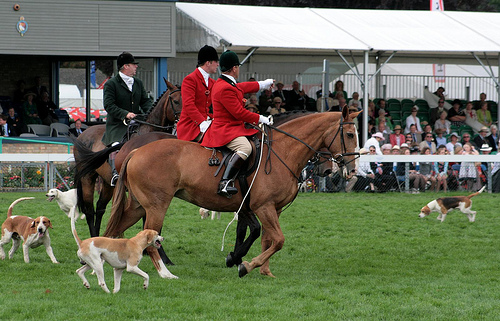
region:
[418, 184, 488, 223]
brown black and white dog on the grass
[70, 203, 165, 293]
brown and white dog on the grass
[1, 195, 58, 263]
brown and white dog on the grass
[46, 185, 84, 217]
white dog on the grass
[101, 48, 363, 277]
man in red riding a light brown horse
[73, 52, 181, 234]
man in black riding a brown and black horse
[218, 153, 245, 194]
a black leather riding boot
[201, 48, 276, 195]
a man in a red riding outfit with black hat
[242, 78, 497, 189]
people in the stands watching the horse riding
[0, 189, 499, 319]
green grass on horse riding field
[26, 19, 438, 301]
Horses on the grass.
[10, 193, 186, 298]
Dogs on the grass.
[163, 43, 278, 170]
Men riding horses on the field.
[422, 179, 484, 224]
Dog in the background.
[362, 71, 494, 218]
people watching the horses.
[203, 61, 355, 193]
Reins on the horse.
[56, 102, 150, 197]
Tail on the horse.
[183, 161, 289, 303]
Legs of the horse.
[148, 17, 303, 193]
Men in red coats.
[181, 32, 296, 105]
Men in black hats.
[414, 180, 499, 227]
Dog smelling the ground.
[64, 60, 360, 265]
Three people on horses.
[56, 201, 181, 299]
Dog next to the horse.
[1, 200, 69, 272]
Dog behind the horses.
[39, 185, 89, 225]
The dog is white.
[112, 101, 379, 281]
The horse is brown.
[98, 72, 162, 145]
The jacket is black.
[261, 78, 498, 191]
Spectators in the background.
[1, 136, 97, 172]
The wall is brick.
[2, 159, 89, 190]
The fence is small.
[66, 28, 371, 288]
Three people on horses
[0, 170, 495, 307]
Dogs are running around the horses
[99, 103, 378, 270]
Horses are brown in color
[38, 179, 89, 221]
Dog in the background's coat is white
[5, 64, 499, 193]
A crowd of people in the background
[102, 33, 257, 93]
Men on horses have black hats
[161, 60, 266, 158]
Two men wearing red coats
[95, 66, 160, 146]
Man on horse is wearing a black coat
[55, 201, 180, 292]
A side view of a dog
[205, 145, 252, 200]
Man on horse is wearing black boots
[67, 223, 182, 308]
mid size dog with light brown and white skin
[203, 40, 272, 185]
horse rider with red coat and black hat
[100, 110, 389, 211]
large muscular brown horse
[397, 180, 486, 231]
a beagle sniffing for biscuit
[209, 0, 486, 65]
white plastic roof over watchers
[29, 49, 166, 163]
a white man with black coat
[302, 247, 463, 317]
green grass with fresh mow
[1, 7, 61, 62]
a clock tower with redish shade and blue frame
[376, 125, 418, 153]
watchers watching dogs race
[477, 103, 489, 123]
a woman with green vest watching